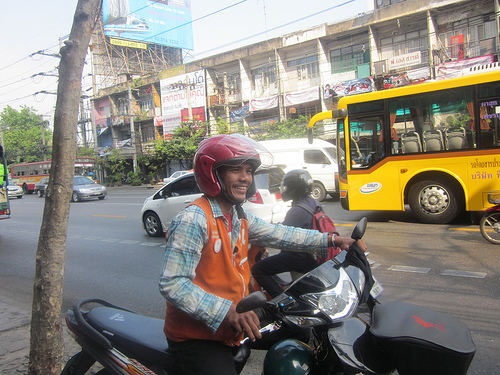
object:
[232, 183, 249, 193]
smile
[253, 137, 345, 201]
van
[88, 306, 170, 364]
seat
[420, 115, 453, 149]
ground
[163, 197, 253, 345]
orange vest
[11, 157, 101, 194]
bus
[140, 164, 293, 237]
car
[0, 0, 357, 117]
power lines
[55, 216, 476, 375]
motorcycle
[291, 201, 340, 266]
backpack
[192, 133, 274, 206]
helmet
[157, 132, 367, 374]
cyclist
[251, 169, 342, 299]
man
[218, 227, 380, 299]
motorcycle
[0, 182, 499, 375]
road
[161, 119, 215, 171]
tree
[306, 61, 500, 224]
bus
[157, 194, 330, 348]
shirt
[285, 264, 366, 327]
head light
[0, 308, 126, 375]
sidewalk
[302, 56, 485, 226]
background